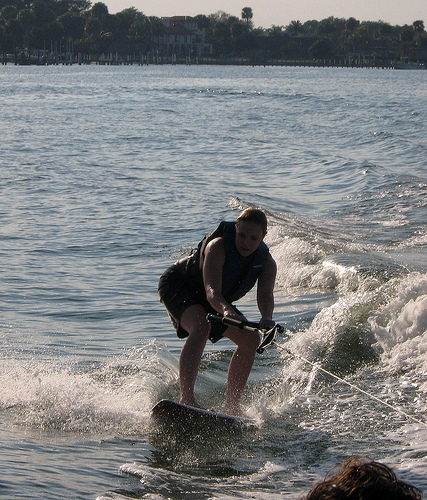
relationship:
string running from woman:
[279, 344, 426, 435] [159, 206, 283, 419]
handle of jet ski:
[212, 305, 280, 337] [137, 310, 418, 459]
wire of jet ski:
[273, 341, 388, 419] [137, 310, 418, 459]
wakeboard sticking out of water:
[148, 397, 265, 430] [0, 60, 425, 500]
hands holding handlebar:
[209, 297, 284, 326] [215, 323, 285, 358]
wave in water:
[207, 195, 424, 462] [1, 60, 425, 497]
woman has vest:
[121, 184, 314, 428] [187, 208, 271, 308]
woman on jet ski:
[159, 206, 283, 419] [153, 393, 261, 437]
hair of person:
[233, 206, 268, 235] [153, 203, 278, 421]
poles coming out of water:
[1, 39, 411, 70] [1, 60, 425, 497]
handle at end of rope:
[206, 311, 281, 331] [283, 343, 374, 398]